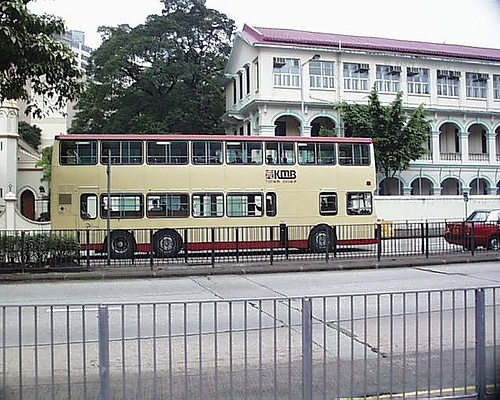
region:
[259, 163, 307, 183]
writing on side of bus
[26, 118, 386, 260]
red and tan double decker bus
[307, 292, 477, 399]
grey metal guard railing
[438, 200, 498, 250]
red car parked on side of street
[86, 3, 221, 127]
large tree covered in green leaves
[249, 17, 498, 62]
red shingles on building roof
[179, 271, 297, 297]
cracks in street pavement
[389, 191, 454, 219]
white concrete wall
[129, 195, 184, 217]
people riding on bus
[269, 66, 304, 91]
white balcony guard rails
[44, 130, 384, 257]
Double decker bus.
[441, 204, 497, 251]
Small red car.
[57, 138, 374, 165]
Second story windows on double decker bus.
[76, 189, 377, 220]
Lower level windows on double decker bus.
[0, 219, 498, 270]
Fence dividing the road.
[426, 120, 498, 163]
Balcony on white building.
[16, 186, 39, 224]
Red door in white building.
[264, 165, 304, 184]
Writing on side of bus.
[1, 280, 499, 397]
Fence on side of the road.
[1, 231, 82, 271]
Bushes near road divider.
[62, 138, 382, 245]
A double decker bus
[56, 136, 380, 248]
The bus is beige and red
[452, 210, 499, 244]
The car is red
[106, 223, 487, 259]
A long fence along the street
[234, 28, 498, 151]
A building with a red roof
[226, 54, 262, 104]
Four windows along a building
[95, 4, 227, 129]
A large green tree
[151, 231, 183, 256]
A single bus tire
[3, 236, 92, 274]
Bushes along a fence.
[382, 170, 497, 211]
A wall along the street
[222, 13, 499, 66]
roof of a building is red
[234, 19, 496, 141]
building is white with red roof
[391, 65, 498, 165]
building has balconies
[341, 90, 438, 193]
a green tree in front a building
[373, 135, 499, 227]
home has a white fence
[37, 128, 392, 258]
a double-decker bus on a road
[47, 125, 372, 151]
roof of double-decker bus is red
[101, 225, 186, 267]
two front wheels of double-decker bus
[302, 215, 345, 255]
back wheel of double-decker bus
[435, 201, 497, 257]
a red car in the street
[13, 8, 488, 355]
a photo of a street scene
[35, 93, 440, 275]
a tan double decker bus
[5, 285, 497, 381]
a gate in the foreground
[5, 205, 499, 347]
street area between two gates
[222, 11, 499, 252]
a white building behind the bus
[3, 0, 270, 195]
trees behind the bus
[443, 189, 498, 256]
a red car in front of the bus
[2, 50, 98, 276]
a white structure behind the bus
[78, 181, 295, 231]
some passengers are on the bus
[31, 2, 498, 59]
looks like a cludy day in the city